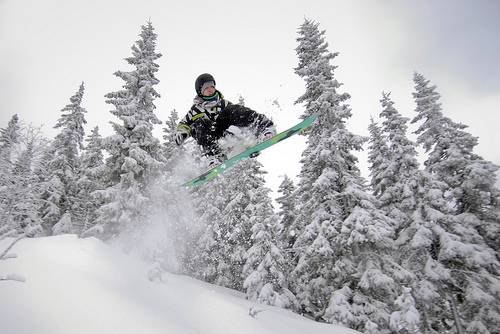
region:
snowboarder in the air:
[180, 70, 321, 202]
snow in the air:
[138, 187, 191, 294]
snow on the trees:
[302, 200, 406, 302]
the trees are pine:
[414, 192, 466, 322]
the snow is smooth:
[28, 265, 66, 309]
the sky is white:
[268, 180, 278, 191]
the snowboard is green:
[217, 138, 277, 185]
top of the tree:
[127, 15, 140, 42]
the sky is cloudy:
[19, 19, 62, 69]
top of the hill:
[22, 220, 62, 255]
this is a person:
[124, 54, 284, 183]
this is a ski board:
[183, 100, 335, 203]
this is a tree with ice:
[99, 12, 170, 200]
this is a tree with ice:
[29, 75, 103, 214]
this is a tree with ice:
[271, 19, 366, 270]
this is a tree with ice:
[363, 77, 421, 279]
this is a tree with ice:
[408, 69, 498, 326]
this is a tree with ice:
[227, 137, 309, 327]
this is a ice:
[13, 227, 245, 332]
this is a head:
[193, 64, 224, 119]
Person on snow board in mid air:
[173, 71, 319, 188]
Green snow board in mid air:
[176, 109, 322, 189]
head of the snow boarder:
[194, 72, 219, 98]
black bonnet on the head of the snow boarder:
[194, 72, 215, 96]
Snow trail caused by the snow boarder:
[90, 153, 203, 289]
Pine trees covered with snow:
[2, 15, 497, 330]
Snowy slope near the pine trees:
[4, 249, 363, 332]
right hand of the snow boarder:
[174, 128, 187, 145]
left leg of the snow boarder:
[227, 105, 275, 138]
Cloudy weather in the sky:
[0, 0, 493, 160]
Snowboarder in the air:
[162, 62, 330, 201]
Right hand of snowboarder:
[165, 125, 195, 148]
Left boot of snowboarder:
[250, 122, 277, 147]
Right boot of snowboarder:
[196, 148, 231, 172]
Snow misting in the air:
[100, 154, 215, 290]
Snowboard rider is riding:
[173, 108, 320, 205]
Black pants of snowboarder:
[187, 102, 259, 155]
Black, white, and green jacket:
[173, 97, 234, 131]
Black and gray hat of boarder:
[191, 70, 215, 94]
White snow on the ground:
[0, 227, 360, 332]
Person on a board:
[170, 112, 333, 194]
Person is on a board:
[174, 108, 321, 204]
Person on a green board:
[177, 103, 321, 198]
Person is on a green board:
[170, 112, 327, 194]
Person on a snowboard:
[179, 110, 330, 192]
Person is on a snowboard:
[175, 107, 325, 205]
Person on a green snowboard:
[174, 111, 326, 191]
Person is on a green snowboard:
[177, 107, 322, 193]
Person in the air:
[169, 67, 346, 194]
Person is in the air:
[165, 66, 326, 198]